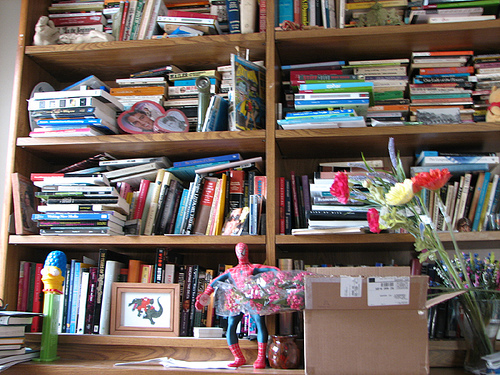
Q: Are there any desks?
A: No, there are no desks.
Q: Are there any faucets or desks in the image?
A: No, there are no desks or faucets.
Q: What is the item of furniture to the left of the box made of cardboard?
A: The piece of furniture is a shelf.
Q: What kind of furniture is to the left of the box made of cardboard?
A: The piece of furniture is a shelf.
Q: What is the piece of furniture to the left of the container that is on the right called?
A: The piece of furniture is a shelf.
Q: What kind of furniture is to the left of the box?
A: The piece of furniture is a shelf.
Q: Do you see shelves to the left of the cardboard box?
A: Yes, there is a shelf to the left of the box.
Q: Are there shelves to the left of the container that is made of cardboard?
A: Yes, there is a shelf to the left of the box.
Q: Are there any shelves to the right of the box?
A: No, the shelf is to the left of the box.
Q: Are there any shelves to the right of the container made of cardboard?
A: No, the shelf is to the left of the box.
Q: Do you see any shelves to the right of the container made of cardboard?
A: No, the shelf is to the left of the box.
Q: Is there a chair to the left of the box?
A: No, there is a shelf to the left of the box.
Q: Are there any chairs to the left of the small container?
A: No, there is a shelf to the left of the box.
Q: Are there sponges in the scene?
A: No, there are no sponges.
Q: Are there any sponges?
A: No, there are no sponges.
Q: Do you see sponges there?
A: No, there are no sponges.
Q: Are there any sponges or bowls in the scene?
A: No, there are no sponges or bowls.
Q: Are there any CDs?
A: No, there are no cds.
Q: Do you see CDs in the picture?
A: No, there are no cds.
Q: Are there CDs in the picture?
A: No, there are no cds.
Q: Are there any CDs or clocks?
A: No, there are no CDs or clocks.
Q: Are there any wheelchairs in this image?
A: No, there are no wheelchairs.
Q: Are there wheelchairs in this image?
A: No, there are no wheelchairs.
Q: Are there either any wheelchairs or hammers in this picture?
A: No, there are no wheelchairs or hammers.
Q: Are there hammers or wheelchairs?
A: No, there are no wheelchairs or hammers.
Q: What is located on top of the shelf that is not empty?
A: The book is on top of the shelf.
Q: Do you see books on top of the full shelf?
A: Yes, there is a book on top of the shelf.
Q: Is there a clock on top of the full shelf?
A: No, there is a book on top of the shelf.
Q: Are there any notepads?
A: No, there are no notepads.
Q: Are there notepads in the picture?
A: No, there are no notepads.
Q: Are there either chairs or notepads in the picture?
A: No, there are no notepads or chairs.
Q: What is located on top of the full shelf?
A: The book is on top of the shelf.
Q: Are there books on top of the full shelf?
A: Yes, there is a book on top of the shelf.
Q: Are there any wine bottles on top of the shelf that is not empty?
A: No, there is a book on top of the shelf.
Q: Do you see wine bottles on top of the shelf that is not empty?
A: No, there is a book on top of the shelf.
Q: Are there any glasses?
A: No, there are no glasses.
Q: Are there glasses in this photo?
A: No, there are no glasses.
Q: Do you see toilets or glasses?
A: No, there are no glasses or toilets.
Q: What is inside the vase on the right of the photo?
A: The flower is inside the vase.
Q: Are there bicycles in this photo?
A: No, there are no bicycles.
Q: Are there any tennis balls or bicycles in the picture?
A: No, there are no bicycles or tennis balls.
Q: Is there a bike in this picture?
A: No, there are no bikes.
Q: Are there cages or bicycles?
A: No, there are no bicycles or cages.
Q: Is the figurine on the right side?
A: Yes, the figurine is on the right of the image.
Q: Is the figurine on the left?
A: No, the figurine is on the right of the image.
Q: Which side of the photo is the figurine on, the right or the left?
A: The figurine is on the right of the image.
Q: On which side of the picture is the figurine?
A: The figurine is on the right of the image.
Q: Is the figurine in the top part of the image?
A: Yes, the figurine is in the top of the image.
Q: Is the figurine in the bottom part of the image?
A: No, the figurine is in the top of the image.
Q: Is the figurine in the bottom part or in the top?
A: The figurine is in the top of the image.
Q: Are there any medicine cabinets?
A: No, there are no medicine cabinets.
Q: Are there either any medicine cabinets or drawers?
A: No, there are no medicine cabinets or drawers.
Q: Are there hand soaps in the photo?
A: No, there are no hand soaps.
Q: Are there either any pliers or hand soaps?
A: No, there are no hand soaps or pliers.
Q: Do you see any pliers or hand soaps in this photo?
A: No, there are no hand soaps or pliers.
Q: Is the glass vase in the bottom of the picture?
A: Yes, the vase is in the bottom of the image.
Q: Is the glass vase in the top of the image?
A: No, the vase is in the bottom of the image.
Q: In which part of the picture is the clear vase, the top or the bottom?
A: The vase is in the bottom of the image.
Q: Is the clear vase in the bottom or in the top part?
A: The vase is in the bottom of the image.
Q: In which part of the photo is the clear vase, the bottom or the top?
A: The vase is in the bottom of the image.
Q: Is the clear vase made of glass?
A: Yes, the vase is made of glass.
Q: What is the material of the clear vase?
A: The vase is made of glass.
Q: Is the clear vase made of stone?
A: No, the vase is made of glass.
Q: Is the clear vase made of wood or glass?
A: The vase is made of glass.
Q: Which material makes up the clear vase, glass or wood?
A: The vase is made of glass.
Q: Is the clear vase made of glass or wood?
A: The vase is made of glass.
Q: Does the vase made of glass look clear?
A: Yes, the vase is clear.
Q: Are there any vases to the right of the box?
A: Yes, there is a vase to the right of the box.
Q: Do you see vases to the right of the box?
A: Yes, there is a vase to the right of the box.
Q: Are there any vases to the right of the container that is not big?
A: Yes, there is a vase to the right of the box.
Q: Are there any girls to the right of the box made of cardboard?
A: No, there is a vase to the right of the box.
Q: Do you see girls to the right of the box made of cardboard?
A: No, there is a vase to the right of the box.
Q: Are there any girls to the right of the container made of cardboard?
A: No, there is a vase to the right of the box.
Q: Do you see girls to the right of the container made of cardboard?
A: No, there is a vase to the right of the box.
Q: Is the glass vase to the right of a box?
A: Yes, the vase is to the right of a box.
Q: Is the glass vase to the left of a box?
A: No, the vase is to the right of a box.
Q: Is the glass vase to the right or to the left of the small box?
A: The vase is to the right of the box.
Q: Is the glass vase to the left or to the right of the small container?
A: The vase is to the right of the box.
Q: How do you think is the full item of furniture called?
A: The piece of furniture is a shelf.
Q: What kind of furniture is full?
A: The furniture is a shelf.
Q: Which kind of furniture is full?
A: The furniture is a shelf.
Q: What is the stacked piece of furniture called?
A: The piece of furniture is a shelf.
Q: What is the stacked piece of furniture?
A: The piece of furniture is a shelf.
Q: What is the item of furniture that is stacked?
A: The piece of furniture is a shelf.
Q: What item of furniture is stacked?
A: The piece of furniture is a shelf.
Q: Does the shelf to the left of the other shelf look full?
A: Yes, the shelf is full.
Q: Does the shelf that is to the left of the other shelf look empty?
A: No, the shelf is full.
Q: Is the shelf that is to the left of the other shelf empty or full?
A: The shelf is full.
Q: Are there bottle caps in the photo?
A: No, there are no bottle caps.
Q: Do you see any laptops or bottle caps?
A: No, there are no bottle caps or laptops.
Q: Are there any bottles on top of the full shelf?
A: No, there is a book on top of the shelf.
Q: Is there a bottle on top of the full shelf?
A: No, there is a book on top of the shelf.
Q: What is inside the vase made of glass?
A: The flower is inside the vase.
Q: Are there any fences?
A: No, there are no fences.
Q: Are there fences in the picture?
A: No, there are no fences.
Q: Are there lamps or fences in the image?
A: No, there are no fences or lamps.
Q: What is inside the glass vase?
A: The flower is inside the vase.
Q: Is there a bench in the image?
A: No, there are no benches.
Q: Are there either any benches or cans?
A: No, there are no benches or cans.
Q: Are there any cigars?
A: No, there are no cigars.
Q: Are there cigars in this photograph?
A: No, there are no cigars.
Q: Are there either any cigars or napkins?
A: No, there are no cigars or napkins.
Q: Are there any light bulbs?
A: No, there are no light bulbs.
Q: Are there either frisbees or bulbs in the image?
A: No, there are no bulbs or frisbees.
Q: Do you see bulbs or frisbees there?
A: No, there are no bulbs or frisbees.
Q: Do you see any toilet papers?
A: No, there are no toilet papers.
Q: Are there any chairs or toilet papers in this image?
A: No, there are no toilet papers or chairs.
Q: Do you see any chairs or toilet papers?
A: No, there are no toilet papers or chairs.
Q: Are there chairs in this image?
A: No, there are no chairs.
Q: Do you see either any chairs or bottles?
A: No, there are no chairs or bottles.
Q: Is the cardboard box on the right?
A: Yes, the box is on the right of the image.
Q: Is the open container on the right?
A: Yes, the box is on the right of the image.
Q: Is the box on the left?
A: No, the box is on the right of the image.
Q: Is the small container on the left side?
A: No, the box is on the right of the image.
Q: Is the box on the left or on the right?
A: The box is on the right of the image.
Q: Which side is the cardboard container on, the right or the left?
A: The box is on the right of the image.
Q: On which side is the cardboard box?
A: The box is on the right of the image.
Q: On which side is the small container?
A: The box is on the right of the image.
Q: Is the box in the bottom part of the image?
A: Yes, the box is in the bottom of the image.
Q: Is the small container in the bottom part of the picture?
A: Yes, the box is in the bottom of the image.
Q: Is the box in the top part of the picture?
A: No, the box is in the bottom of the image.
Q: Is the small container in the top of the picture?
A: No, the box is in the bottom of the image.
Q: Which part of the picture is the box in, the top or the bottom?
A: The box is in the bottom of the image.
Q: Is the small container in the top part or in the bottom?
A: The box is in the bottom of the image.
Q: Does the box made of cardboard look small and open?
A: Yes, the box is small and open.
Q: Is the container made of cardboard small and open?
A: Yes, the box is small and open.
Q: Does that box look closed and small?
A: No, the box is small but open.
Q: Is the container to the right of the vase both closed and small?
A: No, the box is small but open.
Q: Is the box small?
A: Yes, the box is small.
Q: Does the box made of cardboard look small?
A: Yes, the box is small.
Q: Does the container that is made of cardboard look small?
A: Yes, the box is small.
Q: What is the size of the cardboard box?
A: The box is small.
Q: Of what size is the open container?
A: The box is small.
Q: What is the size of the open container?
A: The box is small.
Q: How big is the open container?
A: The box is small.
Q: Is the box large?
A: No, the box is small.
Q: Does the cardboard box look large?
A: No, the box is small.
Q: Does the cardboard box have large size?
A: No, the box is small.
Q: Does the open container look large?
A: No, the box is small.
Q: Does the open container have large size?
A: No, the box is small.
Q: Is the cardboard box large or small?
A: The box is small.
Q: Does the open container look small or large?
A: The box is small.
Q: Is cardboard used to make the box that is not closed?
A: Yes, the box is made of cardboard.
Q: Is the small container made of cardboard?
A: Yes, the box is made of cardboard.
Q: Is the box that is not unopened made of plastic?
A: No, the box is made of cardboard.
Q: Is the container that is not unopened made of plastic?
A: No, the box is made of cardboard.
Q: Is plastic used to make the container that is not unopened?
A: No, the box is made of cardboard.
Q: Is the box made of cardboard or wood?
A: The box is made of cardboard.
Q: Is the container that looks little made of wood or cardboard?
A: The box is made of cardboard.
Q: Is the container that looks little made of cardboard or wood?
A: The box is made of cardboard.